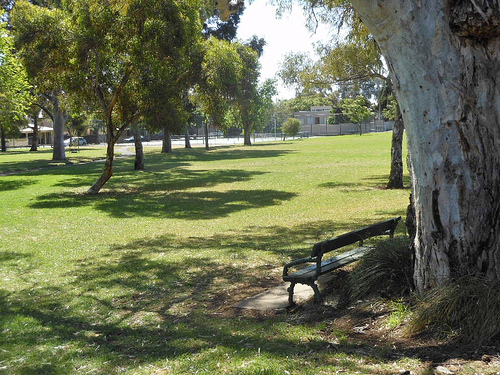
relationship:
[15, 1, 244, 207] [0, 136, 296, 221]
tree cast shadows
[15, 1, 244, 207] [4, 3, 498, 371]
tree in park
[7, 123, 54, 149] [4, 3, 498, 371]
home near park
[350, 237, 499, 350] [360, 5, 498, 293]
grass near tree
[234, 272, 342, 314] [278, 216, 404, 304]
footrest near bench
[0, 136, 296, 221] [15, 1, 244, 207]
shadows cast tree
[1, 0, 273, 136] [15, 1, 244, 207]
leaves on tree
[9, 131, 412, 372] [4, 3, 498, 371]
grass in park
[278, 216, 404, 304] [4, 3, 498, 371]
bench in park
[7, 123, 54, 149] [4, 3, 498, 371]
home in park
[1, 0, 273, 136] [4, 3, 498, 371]
leaves in park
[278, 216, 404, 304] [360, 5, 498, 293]
bench front trees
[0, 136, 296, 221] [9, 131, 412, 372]
shadows on grass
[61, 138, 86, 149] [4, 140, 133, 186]
car on walkway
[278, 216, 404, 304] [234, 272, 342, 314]
bench has cement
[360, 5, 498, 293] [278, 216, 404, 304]
trunk behind bench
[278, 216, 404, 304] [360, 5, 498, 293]
bench underneath bark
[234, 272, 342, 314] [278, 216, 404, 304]
footrest front bench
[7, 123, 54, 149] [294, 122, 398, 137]
home with fence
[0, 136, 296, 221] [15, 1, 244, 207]
shadows of tree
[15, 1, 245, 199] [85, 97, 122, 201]
tree with trunk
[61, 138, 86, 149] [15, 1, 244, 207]
car beyond tree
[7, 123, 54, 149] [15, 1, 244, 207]
home beyond tree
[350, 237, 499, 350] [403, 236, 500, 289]
grass at base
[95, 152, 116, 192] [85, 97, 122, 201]
curving on trunk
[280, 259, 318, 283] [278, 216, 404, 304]
arm on bench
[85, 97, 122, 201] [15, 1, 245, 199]
trunk of tree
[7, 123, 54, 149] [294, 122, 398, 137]
home beyond fence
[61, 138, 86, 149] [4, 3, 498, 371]
car edge park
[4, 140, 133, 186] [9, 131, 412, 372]
walkway through grass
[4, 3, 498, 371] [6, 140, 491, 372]
plant in city park